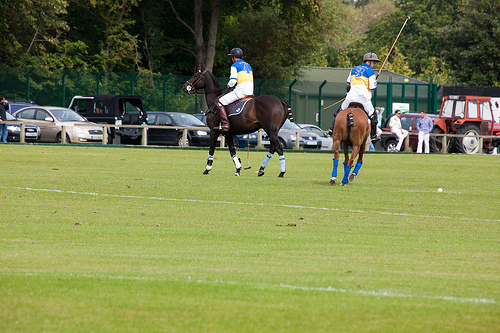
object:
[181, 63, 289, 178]
horse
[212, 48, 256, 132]
rider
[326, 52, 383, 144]
man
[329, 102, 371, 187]
horse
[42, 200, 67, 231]
grass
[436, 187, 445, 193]
ball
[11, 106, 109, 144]
car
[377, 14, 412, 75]
pole